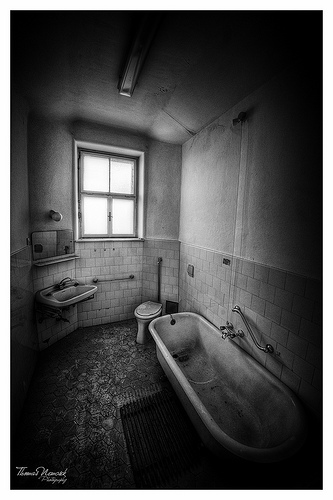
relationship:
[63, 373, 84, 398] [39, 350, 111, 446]
tile on floor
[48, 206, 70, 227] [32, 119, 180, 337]
light on wall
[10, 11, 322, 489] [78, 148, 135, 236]
bathroom has window